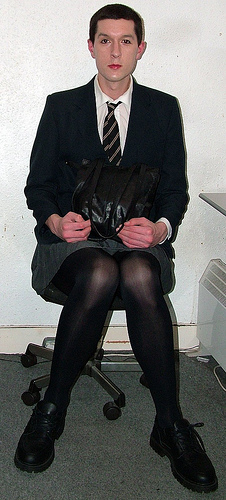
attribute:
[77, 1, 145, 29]
hair — brown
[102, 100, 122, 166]
tie — grey, black, striped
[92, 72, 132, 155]
dress shirt — white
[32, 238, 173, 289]
dress — green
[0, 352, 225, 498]
floor — dark gray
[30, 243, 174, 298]
dress — gray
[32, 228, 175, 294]
dress — green 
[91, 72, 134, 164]
shirt — white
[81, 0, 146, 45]
hair cut — very manly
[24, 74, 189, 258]
jacket — black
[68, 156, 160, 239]
purse — black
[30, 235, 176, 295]
dress — green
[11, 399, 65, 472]
shoe — black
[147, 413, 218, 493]
shoe — black